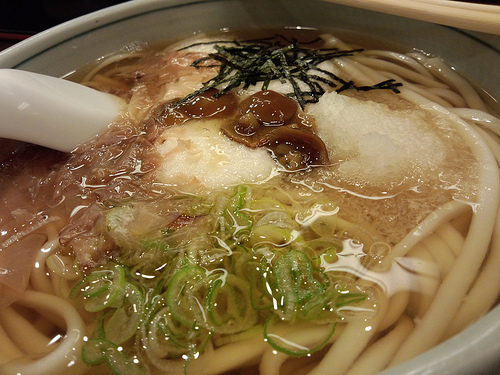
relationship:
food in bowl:
[2, 26, 497, 373] [2, 4, 496, 371]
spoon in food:
[0, 61, 131, 159] [2, 26, 497, 373]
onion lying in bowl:
[262, 315, 337, 358] [2, 4, 496, 371]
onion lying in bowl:
[206, 277, 249, 324] [2, 4, 496, 371]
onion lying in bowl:
[164, 264, 206, 332] [2, 4, 496, 371]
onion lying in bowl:
[144, 301, 201, 356] [2, 4, 496, 371]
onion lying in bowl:
[82, 264, 124, 314] [2, 4, 496, 371]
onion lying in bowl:
[79, 330, 131, 370] [2, 4, 496, 371]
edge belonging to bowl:
[24, 23, 72, 53] [2, 4, 496, 371]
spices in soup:
[185, 26, 402, 102] [0, 15, 499, 373]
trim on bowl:
[63, 12, 125, 50] [1, 13, 183, 80]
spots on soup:
[115, 345, 122, 351] [0, 15, 499, 373]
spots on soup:
[365, 325, 371, 332] [0, 15, 499, 373]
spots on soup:
[307, 352, 311, 357] [0, 15, 499, 373]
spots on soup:
[271, 350, 277, 355] [0, 15, 499, 373]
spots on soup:
[212, 302, 217, 307] [0, 15, 499, 373]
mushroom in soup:
[263, 124, 330, 173] [0, 15, 499, 373]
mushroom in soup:
[220, 86, 299, 148] [0, 15, 499, 373]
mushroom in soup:
[150, 81, 240, 128] [0, 15, 499, 373]